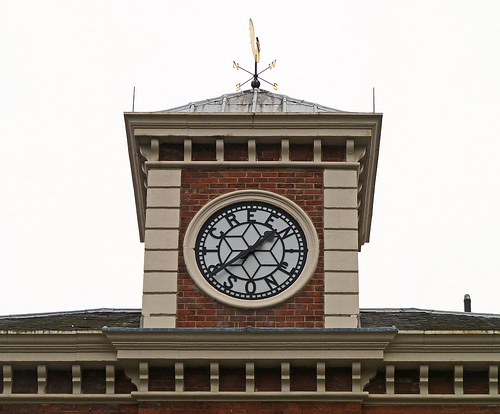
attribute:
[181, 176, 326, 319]
clock — on front, white, black, lettered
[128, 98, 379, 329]
tower — brick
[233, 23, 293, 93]
weather vane — metal, black, gold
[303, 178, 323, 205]
bricks — brown, red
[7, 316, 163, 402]
building — bricked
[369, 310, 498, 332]
roof — shingled, black, metal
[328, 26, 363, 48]
sky — gray, white, clear, cloudy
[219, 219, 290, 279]
clock hands — black